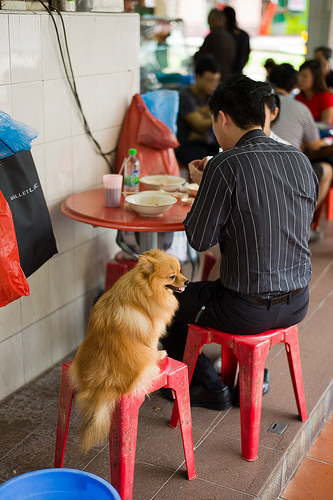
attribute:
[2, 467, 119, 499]
container — blue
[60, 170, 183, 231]
table food — round, small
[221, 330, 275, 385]
stool — red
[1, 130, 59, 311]
bag — black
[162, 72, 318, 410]
guy — black and white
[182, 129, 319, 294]
shirt — striped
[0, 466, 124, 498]
bucket — blue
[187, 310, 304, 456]
stool — red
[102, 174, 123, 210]
cup — plastic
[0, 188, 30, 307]
bag — plastic, orange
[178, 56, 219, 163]
person — eating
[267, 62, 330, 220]
person — eating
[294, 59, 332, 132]
person — eating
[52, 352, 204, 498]
stool — red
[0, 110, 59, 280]
bag — black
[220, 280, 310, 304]
belt — black